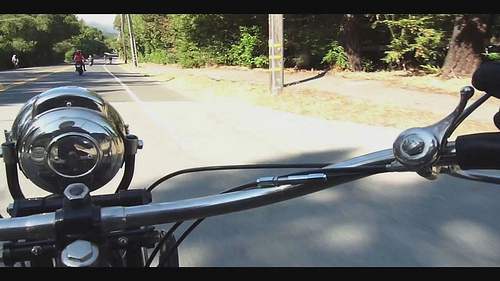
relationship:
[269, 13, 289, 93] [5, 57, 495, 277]
pole by road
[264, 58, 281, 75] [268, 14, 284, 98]
line on pole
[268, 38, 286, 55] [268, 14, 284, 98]
line on pole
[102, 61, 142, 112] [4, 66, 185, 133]
line along road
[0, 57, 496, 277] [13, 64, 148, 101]
road beside road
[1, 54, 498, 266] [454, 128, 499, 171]
bike has handle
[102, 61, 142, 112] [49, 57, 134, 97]
line in center of road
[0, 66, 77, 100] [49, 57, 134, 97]
line in center of road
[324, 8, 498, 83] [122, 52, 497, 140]
tree next to sidewalk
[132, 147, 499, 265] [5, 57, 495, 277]
shadow on road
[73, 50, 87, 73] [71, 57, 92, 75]
motorcyclist riding motorcycle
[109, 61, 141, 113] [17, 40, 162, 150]
line on road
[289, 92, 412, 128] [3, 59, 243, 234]
grass near road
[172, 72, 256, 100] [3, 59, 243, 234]
grass near road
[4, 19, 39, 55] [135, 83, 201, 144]
tree beside road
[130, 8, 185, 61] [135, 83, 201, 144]
tree beside road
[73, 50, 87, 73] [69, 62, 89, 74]
motorcyclist on a motorcycle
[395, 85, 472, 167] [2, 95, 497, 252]
brake on handle bar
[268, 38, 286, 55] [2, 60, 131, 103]
line on street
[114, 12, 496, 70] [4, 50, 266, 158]
trees on side of road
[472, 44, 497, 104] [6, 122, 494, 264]
hand on handlebar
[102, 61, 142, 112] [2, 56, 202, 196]
line on street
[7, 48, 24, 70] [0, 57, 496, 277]
person on road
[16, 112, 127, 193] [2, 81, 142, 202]
back of headlight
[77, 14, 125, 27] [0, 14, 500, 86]
sky above trees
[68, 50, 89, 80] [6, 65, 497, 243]
motorbike on road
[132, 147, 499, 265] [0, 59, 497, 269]
shadow on ground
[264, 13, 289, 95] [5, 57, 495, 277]
pole on side of road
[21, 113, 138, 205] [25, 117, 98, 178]
reflection of motorcyclist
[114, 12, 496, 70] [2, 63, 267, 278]
trees on side of road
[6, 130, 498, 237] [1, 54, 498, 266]
handlebar of bike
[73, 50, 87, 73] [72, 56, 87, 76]
motorcyclist on back of motorcycle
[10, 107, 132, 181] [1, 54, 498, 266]
mirror on front of bike